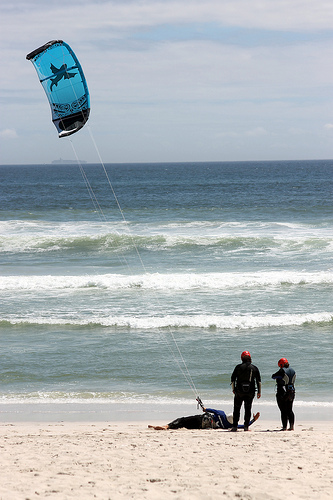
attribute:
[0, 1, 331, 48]
cloud — layered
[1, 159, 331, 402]
water — blue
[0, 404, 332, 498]
beach — very sandy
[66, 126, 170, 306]
lines — white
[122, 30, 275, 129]
sky — blue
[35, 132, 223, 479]
picture — Day time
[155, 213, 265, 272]
whte waves — white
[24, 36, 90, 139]
kite — blue, black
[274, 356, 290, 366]
helmet — red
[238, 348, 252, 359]
helmet — red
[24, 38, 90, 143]
parasail — blue, black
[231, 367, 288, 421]
suits — wet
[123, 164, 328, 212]
water — blue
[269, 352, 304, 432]
wetsuit — blue 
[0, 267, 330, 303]
waves — white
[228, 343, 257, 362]
helmet — red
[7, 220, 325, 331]
foam — white